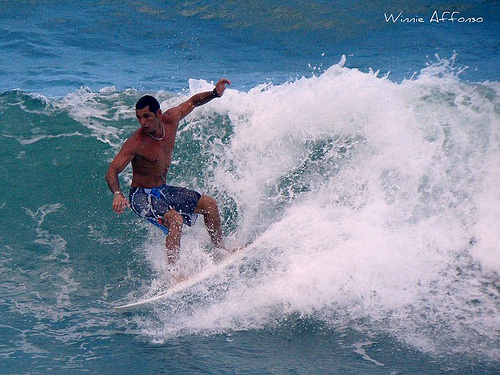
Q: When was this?
A: Daytime.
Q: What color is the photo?
A: Blue.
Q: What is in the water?
A: Waves.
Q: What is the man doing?
A: Surfer.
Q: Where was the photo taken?
A: Waterbody.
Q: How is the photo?
A: Clear.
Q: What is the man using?
A: A surfboard.